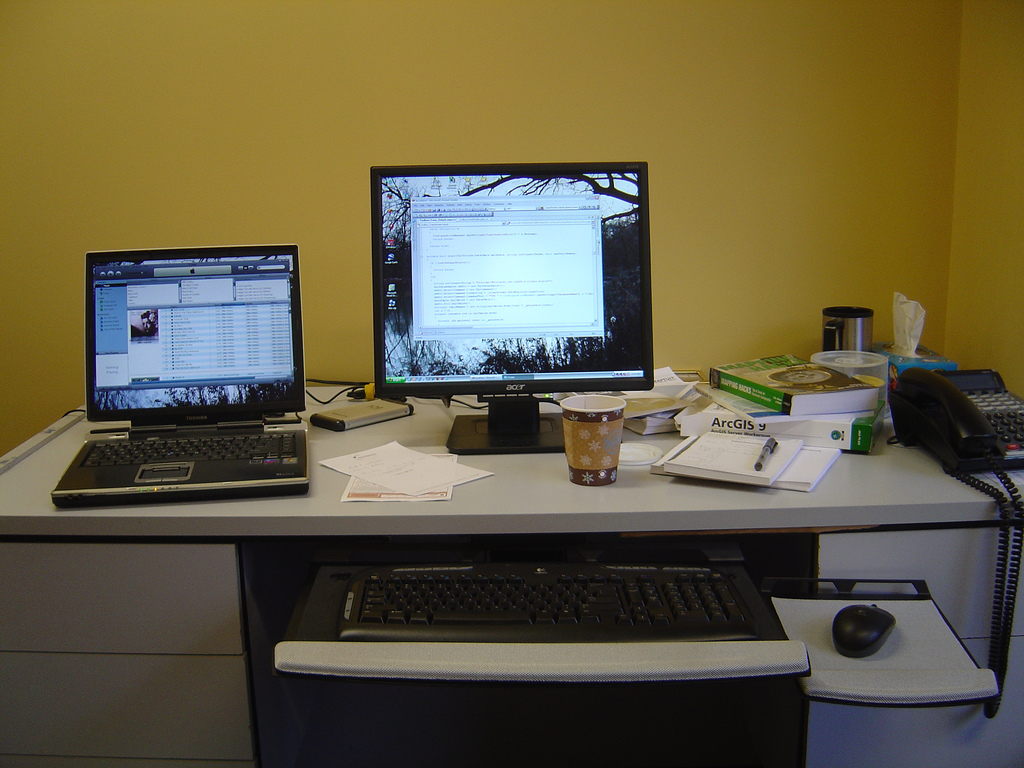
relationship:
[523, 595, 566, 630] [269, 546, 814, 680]
key on keyboard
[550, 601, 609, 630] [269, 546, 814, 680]
key on keyboard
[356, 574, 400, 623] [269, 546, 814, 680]
keys are on keyboard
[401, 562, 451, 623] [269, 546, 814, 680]
keys are on keyboard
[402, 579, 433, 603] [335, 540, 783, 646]
key on keyboard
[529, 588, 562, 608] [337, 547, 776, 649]
key on keyboard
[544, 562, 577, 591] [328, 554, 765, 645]
key on keyboard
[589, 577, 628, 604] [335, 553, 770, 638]
key on keyboard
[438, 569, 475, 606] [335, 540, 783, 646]
key on keyboard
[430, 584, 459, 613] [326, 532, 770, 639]
key on keyboard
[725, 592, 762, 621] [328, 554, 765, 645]
key on keyboard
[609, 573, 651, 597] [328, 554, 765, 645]
key on keyboard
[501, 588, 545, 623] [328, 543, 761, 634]
key on keyboard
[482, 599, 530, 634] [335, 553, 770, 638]
key on keyboard